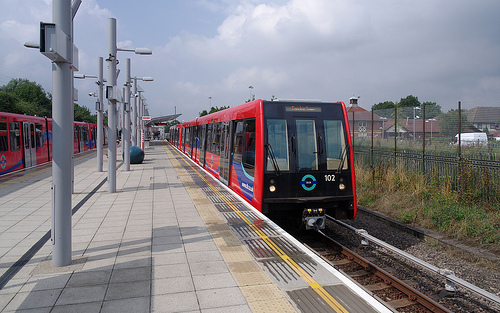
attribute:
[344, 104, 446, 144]
home — distant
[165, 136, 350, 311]
strip — safety, textured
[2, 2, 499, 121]
sky — more clear, ominous, gray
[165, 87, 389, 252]
trai — red, blue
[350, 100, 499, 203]
fencing — tall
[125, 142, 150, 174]
ball — blue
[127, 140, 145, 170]
green object — round, blue-green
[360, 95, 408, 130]
ground — overgrown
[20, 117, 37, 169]
door — sliding, double, grey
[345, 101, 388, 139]
building — light brown, square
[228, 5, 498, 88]
clouds — large, white, grey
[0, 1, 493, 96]
cloud — grey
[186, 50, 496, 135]
cloud — grey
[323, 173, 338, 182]
number — 102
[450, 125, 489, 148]
van — white paneled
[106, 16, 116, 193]
pole — gray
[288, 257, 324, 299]
line — caution, yellow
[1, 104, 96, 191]
train — red, blue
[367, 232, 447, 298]
tracks — brown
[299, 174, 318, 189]
circle — light blue, dark blue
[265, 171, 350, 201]
background — black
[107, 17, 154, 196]
pole — silver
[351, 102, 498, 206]
fence — tall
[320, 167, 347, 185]
number 102 — white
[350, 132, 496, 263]
grass — tall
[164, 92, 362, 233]
train — red, black